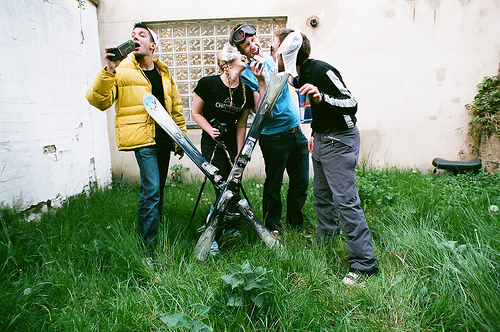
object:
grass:
[69, 236, 163, 309]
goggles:
[227, 25, 257, 42]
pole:
[186, 173, 209, 230]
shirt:
[240, 60, 301, 135]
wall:
[359, 18, 485, 118]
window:
[136, 19, 289, 127]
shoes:
[338, 265, 379, 290]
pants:
[199, 127, 238, 183]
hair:
[214, 52, 253, 109]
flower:
[481, 200, 499, 213]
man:
[227, 21, 311, 241]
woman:
[190, 42, 253, 225]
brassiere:
[273, 29, 303, 78]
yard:
[4, 166, 499, 330]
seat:
[432, 156, 481, 172]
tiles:
[153, 23, 234, 77]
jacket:
[85, 57, 187, 154]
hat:
[222, 42, 240, 68]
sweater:
[292, 57, 358, 133]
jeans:
[133, 142, 171, 264]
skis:
[142, 94, 294, 263]